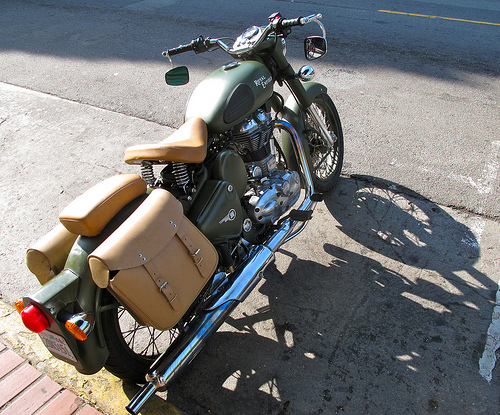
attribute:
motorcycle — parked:
[30, 2, 367, 414]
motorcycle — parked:
[12, 19, 387, 399]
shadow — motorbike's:
[165, 170, 498, 413]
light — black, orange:
[60, 310, 93, 347]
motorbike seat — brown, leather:
[130, 136, 215, 168]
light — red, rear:
[19, 293, 48, 337]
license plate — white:
[35, 327, 76, 359]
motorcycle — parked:
[3, 11, 347, 412]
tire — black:
[290, 93, 342, 200]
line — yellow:
[367, 2, 499, 44]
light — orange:
[261, 10, 293, 48]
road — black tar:
[1, 0, 498, 222]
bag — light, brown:
[103, 162, 210, 364]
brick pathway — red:
[2, 346, 106, 413]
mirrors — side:
[306, 33, 330, 60]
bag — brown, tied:
[85, 187, 221, 328]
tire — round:
[275, 90, 341, 193]